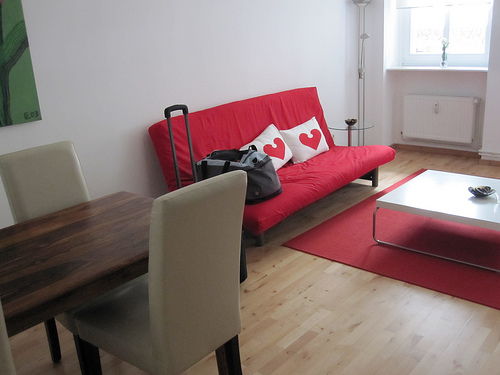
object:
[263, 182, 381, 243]
shadow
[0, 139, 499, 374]
floor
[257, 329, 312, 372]
lines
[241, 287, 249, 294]
small spots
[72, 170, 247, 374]
chair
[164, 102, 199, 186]
handle on luggage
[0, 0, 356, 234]
wall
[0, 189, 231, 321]
table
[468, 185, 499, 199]
ash tray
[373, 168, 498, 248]
table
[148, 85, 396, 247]
sofa bed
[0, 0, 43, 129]
painting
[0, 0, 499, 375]
room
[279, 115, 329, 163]
pillow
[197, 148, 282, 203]
bag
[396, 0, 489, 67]
big window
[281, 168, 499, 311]
carpet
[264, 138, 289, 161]
red heart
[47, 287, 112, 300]
edge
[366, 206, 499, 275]
stand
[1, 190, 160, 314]
top of table